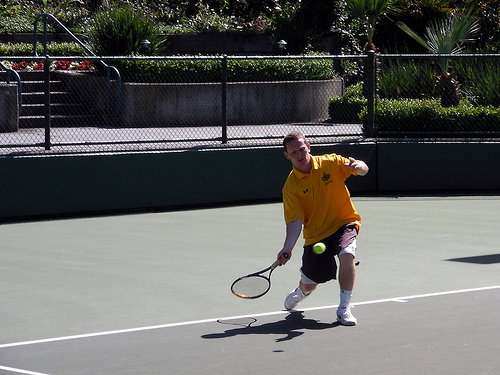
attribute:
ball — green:
[312, 242, 326, 254]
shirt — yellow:
[282, 153, 361, 247]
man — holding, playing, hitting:
[276, 132, 369, 327]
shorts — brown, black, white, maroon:
[297, 221, 359, 285]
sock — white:
[338, 289, 353, 311]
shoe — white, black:
[336, 305, 357, 326]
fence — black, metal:
[2, 54, 498, 160]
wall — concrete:
[4, 76, 344, 132]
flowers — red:
[11, 61, 91, 72]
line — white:
[1, 284, 500, 346]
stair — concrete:
[0, 61, 99, 129]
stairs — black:
[4, 66, 97, 128]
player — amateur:
[277, 129, 371, 326]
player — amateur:
[272, 132, 370, 333]